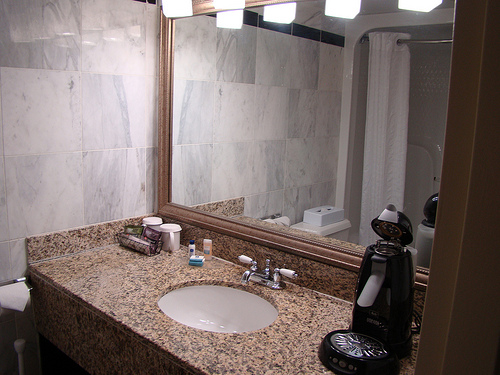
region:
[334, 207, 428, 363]
This is a coffee maker.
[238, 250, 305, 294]
There is two handles on the faucet.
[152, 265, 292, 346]
The sinks color is white.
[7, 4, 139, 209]
These are marble walls.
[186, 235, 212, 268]
These are soaps you can use.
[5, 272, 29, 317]
This is a toilet paper roll.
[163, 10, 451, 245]
The mirror is reflecting the shower.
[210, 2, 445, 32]
There are four lights.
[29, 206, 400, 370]
There is only one sink.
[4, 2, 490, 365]
This is a bathroom.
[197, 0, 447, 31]
four lights above mirror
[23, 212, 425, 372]
granite bathroom counter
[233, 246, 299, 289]
silver faucet with white handles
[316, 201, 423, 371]
black water dispenser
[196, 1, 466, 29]
lights reflected in mirror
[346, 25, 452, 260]
partial view of shower in mirror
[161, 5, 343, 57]
single black strip on black wall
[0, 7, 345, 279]
white marble tile walls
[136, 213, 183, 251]
two cups at corner of counter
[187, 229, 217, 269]
toiletries on left of sink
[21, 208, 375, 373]
counter of sink is brown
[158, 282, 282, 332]
sink inside is white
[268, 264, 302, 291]
right handle is color white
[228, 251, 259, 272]
left handle is color white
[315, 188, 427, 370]
soap dispenser on side of counter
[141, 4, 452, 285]
mirror in front of sink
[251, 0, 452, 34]
lights reflected on a mirror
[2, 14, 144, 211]
wall of bathroom are color gray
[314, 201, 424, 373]
soap dispenser is black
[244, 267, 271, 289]
faucet of sink is silver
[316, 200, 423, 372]
a black coffee maker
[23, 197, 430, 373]
a brown marble vanity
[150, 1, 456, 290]
a wall mounted mirror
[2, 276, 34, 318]
a roll of toilet paper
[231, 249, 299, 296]
a bathroom faucet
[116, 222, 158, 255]
a basket of complimentary soaps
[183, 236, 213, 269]
a group of complimentary soaps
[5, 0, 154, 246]
white marble wall tile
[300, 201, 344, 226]
a white box of kleenex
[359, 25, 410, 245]
a reflection of white shower curtains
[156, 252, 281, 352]
the sink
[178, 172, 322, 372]
the sink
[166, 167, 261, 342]
the sink